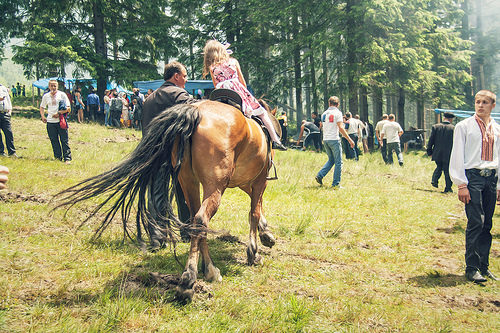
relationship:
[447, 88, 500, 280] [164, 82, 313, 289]
man walking horse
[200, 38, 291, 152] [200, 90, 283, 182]
girl seated on a horse back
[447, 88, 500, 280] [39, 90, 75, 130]
man in a ankara shirt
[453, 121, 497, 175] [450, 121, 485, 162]
luxury of shirt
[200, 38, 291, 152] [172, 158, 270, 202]
girl riding horse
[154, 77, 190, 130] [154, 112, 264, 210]
man escorts girl riding horse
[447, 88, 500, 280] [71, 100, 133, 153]
man are under tree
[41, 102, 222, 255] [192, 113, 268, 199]
long tail of horse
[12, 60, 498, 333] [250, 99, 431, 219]
riding horse amongst crowd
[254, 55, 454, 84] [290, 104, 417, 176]
trees in mist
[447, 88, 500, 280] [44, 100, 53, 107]
man standing watching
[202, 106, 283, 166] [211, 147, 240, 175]
coat of horse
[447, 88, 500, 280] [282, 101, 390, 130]
man going under trees for event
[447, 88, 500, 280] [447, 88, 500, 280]
man going under trees for man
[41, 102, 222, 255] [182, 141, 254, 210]
long tail of horse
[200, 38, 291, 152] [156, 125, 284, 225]
girl riding horse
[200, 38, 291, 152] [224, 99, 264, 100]
girl wearing dress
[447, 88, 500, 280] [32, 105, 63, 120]
man wearing t-shirt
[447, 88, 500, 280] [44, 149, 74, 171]
man wearing pants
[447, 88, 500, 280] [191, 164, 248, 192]
man in  tshirt walking beside horse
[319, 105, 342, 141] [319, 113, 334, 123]
shirt with flag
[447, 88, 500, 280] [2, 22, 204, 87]
man sitting next to trees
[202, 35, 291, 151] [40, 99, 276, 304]
girl riding brown horse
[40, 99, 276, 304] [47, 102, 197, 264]
brown horse has tail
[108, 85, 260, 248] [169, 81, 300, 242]
long tail on a horse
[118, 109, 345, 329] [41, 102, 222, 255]
brown horse with long tail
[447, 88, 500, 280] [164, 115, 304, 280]
man standing next to horse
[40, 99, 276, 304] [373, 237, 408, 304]
brown horse riding in grass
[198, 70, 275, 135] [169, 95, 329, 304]
saddle on horse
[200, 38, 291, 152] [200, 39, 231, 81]
girl with hair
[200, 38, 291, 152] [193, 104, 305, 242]
girl on a horse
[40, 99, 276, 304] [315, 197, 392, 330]
brown horse in a field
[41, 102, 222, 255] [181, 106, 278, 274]
long tail on horse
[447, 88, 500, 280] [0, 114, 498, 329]
man standing in a field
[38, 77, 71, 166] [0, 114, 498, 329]
man standing in a field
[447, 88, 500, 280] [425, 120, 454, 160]
man in jacket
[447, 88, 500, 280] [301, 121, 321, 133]
man in shirt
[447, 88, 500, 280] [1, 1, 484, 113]
man standing far back